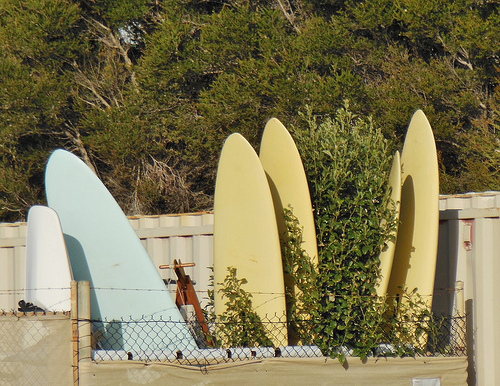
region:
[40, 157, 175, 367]
a light blue surfboard sticking out of a planter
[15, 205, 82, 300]
a small white surfboard sticking out of a planter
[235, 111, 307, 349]
two yellow surfboards extending from a planter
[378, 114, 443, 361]
two yellow surfboards in a planter next to a wall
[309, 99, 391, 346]
a large green bush between yellow surfboards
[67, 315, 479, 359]
a wire fence in front of a planter filled with surfboards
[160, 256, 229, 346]
a brown metal pulley between a blue and yellow surfboard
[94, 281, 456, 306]
a length of barbed wire in front of a row of surfboards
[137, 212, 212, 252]
a beige metal wall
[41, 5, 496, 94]
an expanse of green trees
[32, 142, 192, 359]
a light blue surfboard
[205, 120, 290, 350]
a light yellow surfboard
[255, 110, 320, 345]
a light yellow surfboard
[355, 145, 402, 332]
a light yellow surfboard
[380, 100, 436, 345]
a light yellow surfboard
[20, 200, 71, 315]
a short white surfboard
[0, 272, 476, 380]
metal wire fencing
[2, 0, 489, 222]
a group of trees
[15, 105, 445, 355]
a group of standing surfboards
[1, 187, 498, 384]
a white metal wall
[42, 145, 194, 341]
A light blue board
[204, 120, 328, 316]
A pair of yellow boards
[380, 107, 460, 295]
a pair of yellow boards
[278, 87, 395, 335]
A shrub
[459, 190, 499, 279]
A fence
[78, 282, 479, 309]
barbed wire on a fence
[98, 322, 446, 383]
A chain link fence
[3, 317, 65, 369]
Tarp covering a fence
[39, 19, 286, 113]
wooded area in the background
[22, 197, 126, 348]
The top half of a white board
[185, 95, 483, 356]
the surfboards are yellow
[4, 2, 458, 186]
the trees are green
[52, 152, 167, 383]
the surfboard is blue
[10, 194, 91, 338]
the surfboard is white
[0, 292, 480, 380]
a fence is in front of the surfboards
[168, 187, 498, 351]
the structure behind surfboards is brown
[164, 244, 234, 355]
red object between blue and yellow surfboard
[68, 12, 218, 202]
the branches are brown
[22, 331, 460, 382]
the ground is brown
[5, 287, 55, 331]
black object in front of white surfboard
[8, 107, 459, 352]
group of colorful surfboards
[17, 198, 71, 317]
small white surfboard on end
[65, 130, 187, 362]
sky blue board on left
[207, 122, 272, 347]
pale yellow surfboard in middle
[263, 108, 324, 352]
pale yellow surfboard almost hidden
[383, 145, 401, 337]
smaller pale yellow surfboard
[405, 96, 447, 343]
pale yellow board on right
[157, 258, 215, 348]
wooden object behind fence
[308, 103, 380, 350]
tall green shrubbery with surfboards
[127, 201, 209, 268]
metal building enclosure